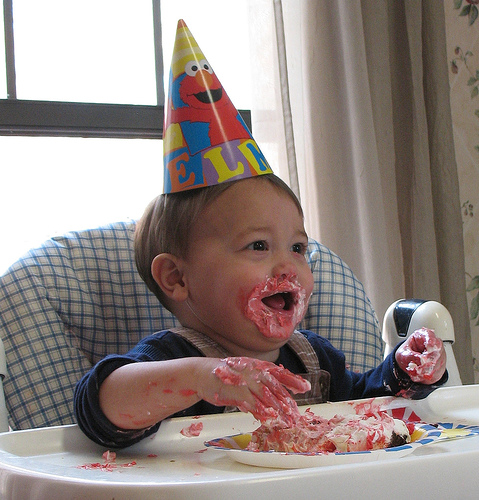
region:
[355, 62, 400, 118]
part of a curtain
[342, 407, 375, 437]
part of a cream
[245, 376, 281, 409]
part of a hand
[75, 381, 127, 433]
edge of a sleeve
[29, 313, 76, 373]
part of a cloth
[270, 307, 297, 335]
part of a mouth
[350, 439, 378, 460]
edge of a plate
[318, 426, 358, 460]
edge of a cake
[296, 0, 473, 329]
The curtains are tan.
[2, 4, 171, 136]
Light shining through window.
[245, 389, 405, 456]
the cake is red.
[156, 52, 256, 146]
Elmo on party hat.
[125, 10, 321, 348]
Baby wearing party hat.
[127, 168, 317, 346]
The baby is a boy.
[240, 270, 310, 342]
Cake on the babies face.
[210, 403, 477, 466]
Cake on a plate.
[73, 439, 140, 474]
Frosting on the table.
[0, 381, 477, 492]
The table is white.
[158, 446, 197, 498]
the table is white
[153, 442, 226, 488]
the table is white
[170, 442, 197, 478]
the table is white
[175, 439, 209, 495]
the table is white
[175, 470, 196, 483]
the table is white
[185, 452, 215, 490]
the table is white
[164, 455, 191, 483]
the table is white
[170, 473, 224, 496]
the table is white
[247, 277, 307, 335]
the red and white frosting on the boy's face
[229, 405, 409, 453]
the cake slice on the paper plate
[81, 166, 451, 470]
a baby sitting in a high chair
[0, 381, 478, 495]
the white tray of the high chair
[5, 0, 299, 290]
the open window behind the high chair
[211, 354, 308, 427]
frosting all over the boy's hand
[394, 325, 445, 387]
and there is frosting on the left hand as well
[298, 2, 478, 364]
the curtain next to the window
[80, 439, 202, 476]
frosting on the tray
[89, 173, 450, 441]
a very happy little boy on his birthday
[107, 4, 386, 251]
the cap is cone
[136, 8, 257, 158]
the cap is cone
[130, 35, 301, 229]
the cap is cone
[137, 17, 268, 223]
the cap is conethe cap is cone